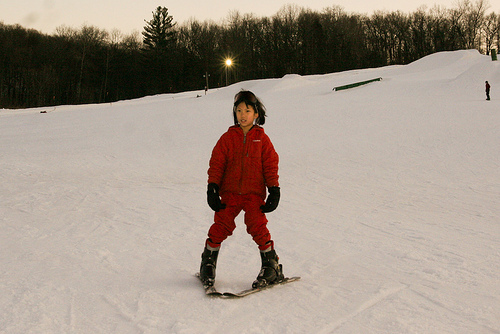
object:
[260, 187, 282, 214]
glove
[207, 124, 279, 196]
jacket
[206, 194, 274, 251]
pants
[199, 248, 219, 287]
shoes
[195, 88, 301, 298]
child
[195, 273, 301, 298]
skis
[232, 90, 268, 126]
hair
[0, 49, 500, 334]
snow